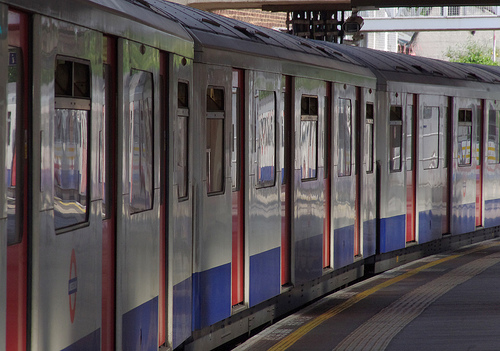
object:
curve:
[171, 228, 499, 349]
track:
[210, 256, 488, 348]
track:
[259, 247, 459, 348]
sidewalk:
[224, 226, 497, 350]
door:
[28, 23, 117, 350]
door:
[117, 39, 162, 349]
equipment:
[286, 6, 364, 44]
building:
[355, 6, 498, 22]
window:
[435, 4, 462, 14]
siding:
[366, 30, 498, 64]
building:
[355, 5, 399, 54]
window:
[336, 95, 351, 178]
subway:
[2, 3, 498, 350]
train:
[8, 3, 498, 346]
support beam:
[290, 21, 499, 28]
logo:
[66, 250, 79, 326]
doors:
[230, 69, 246, 311]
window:
[177, 82, 190, 199]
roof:
[88, 1, 499, 91]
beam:
[264, 2, 499, 45]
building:
[222, 0, 288, 30]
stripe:
[267, 235, 497, 349]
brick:
[377, 329, 389, 340]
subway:
[371, 7, 499, 30]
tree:
[448, 31, 499, 67]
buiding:
[408, 8, 496, 60]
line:
[59, 198, 497, 350]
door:
[228, 70, 247, 310]